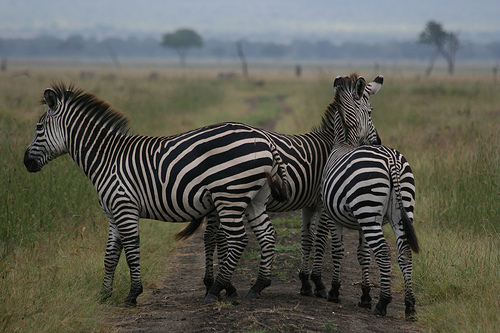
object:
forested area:
[2, 31, 497, 76]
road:
[162, 236, 296, 330]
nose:
[22, 158, 42, 169]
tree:
[418, 20, 463, 76]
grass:
[3, 74, 500, 331]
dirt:
[141, 226, 395, 330]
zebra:
[23, 81, 291, 309]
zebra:
[173, 74, 383, 306]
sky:
[0, 0, 498, 40]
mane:
[38, 80, 132, 135]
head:
[23, 88, 71, 173]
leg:
[112, 209, 144, 309]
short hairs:
[65, 82, 126, 128]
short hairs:
[333, 88, 347, 128]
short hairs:
[320, 101, 337, 131]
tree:
[159, 27, 204, 63]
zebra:
[320, 72, 421, 322]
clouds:
[0, 16, 482, 43]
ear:
[43, 88, 59, 111]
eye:
[35, 122, 43, 132]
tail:
[398, 206, 422, 255]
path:
[136, 83, 408, 329]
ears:
[351, 75, 367, 100]